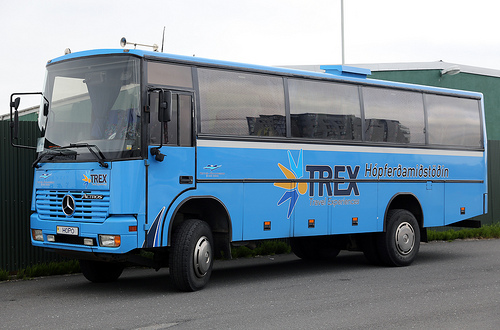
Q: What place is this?
A: It is a road.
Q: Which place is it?
A: It is a road.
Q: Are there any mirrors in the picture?
A: Yes, there is a mirror.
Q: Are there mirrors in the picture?
A: Yes, there is a mirror.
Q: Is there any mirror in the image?
A: Yes, there is a mirror.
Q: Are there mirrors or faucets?
A: Yes, there is a mirror.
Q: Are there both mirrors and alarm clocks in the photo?
A: No, there is a mirror but no alarm clocks.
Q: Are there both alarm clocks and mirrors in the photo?
A: No, there is a mirror but no alarm clocks.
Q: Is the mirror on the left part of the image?
A: Yes, the mirror is on the left of the image.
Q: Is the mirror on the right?
A: No, the mirror is on the left of the image.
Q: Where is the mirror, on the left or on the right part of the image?
A: The mirror is on the left of the image.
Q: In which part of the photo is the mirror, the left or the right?
A: The mirror is on the left of the image.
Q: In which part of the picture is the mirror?
A: The mirror is on the left of the image.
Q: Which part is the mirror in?
A: The mirror is on the left of the image.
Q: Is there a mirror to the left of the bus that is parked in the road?
A: Yes, there is a mirror to the left of the bus.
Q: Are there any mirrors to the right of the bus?
A: No, the mirror is to the left of the bus.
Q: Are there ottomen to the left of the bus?
A: No, there is a mirror to the left of the bus.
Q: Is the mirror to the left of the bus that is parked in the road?
A: Yes, the mirror is to the left of the bus.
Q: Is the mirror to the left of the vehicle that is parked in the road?
A: Yes, the mirror is to the left of the bus.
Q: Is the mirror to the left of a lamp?
A: No, the mirror is to the left of the bus.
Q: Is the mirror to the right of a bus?
A: No, the mirror is to the left of a bus.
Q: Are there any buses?
A: Yes, there is a bus.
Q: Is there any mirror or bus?
A: Yes, there is a bus.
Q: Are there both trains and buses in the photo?
A: No, there is a bus but no trains.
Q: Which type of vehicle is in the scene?
A: The vehicle is a bus.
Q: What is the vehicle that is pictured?
A: The vehicle is a bus.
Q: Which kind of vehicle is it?
A: The vehicle is a bus.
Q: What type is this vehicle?
A: That is a bus.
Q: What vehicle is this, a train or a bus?
A: That is a bus.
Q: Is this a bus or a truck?
A: This is a bus.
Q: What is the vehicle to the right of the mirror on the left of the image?
A: The vehicle is a bus.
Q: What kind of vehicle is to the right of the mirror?
A: The vehicle is a bus.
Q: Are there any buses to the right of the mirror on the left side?
A: Yes, there is a bus to the right of the mirror.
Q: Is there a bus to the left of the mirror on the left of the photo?
A: No, the bus is to the right of the mirror.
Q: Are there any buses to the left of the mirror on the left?
A: No, the bus is to the right of the mirror.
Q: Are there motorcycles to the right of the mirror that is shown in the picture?
A: No, there is a bus to the right of the mirror.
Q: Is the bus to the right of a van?
A: No, the bus is to the right of the mirror.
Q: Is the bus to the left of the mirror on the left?
A: No, the bus is to the right of the mirror.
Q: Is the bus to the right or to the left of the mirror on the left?
A: The bus is to the right of the mirror.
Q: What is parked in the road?
A: The bus is parked in the road.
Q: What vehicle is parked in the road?
A: The vehicle is a bus.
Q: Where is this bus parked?
A: The bus is parked in the road.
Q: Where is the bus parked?
A: The bus is parked in the road.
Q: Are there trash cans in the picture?
A: No, there are no trash cans.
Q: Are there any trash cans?
A: No, there are no trash cans.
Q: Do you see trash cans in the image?
A: No, there are no trash cans.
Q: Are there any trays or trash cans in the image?
A: No, there are no trash cans or trays.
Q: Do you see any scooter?
A: No, there are no scooters.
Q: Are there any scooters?
A: No, there are no scooters.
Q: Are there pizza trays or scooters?
A: No, there are no scooters or pizza trays.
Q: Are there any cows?
A: No, there are no cows.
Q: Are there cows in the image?
A: No, there are no cows.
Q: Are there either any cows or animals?
A: No, there are no cows or animals.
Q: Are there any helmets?
A: No, there are no helmets.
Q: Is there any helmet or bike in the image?
A: No, there are no helmets or bikes.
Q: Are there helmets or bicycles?
A: No, there are no helmets or bicycles.